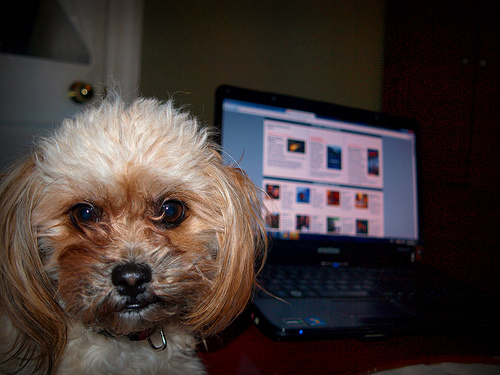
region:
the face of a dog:
[14, 95, 309, 372]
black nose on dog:
[110, 258, 147, 300]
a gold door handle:
[63, 72, 97, 114]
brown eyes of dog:
[49, 184, 229, 246]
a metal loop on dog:
[136, 328, 185, 363]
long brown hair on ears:
[183, 152, 286, 357]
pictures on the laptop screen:
[251, 119, 421, 240]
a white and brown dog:
[0, 83, 232, 372]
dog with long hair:
[1, 108, 266, 358]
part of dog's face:
[93, 246, 169, 329]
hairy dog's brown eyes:
[53, 178, 202, 247]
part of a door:
[15, 17, 155, 157]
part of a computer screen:
[243, 80, 348, 255]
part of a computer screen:
[210, 73, 264, 254]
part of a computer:
[287, 218, 388, 338]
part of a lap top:
[194, 50, 357, 372]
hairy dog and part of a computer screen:
[18, 45, 297, 354]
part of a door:
[46, 57, 113, 124]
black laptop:
[205, 100, 477, 366]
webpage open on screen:
[223, 107, 414, 238]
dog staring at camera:
[15, 102, 250, 373]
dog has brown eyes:
[49, 191, 190, 226]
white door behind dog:
[5, 56, 140, 197]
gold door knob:
[65, 80, 92, 101]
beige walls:
[140, 0, 375, 155]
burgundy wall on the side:
[380, 5, 495, 374]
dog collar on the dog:
[85, 320, 175, 350]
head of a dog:
[25, 107, 256, 329]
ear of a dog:
[6, 139, 76, 232]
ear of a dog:
[188, 162, 264, 252]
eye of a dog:
[51, 199, 116, 235]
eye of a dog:
[135, 187, 205, 247]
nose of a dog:
[108, 262, 165, 304]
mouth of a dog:
[90, 287, 181, 340]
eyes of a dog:
[62, 177, 220, 247]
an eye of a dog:
[53, 194, 117, 239]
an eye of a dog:
[142, 161, 206, 229]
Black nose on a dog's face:
[106, 259, 155, 298]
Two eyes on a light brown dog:
[70, 196, 187, 226]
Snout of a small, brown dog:
[63, 244, 193, 330]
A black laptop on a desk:
[214, 78, 473, 341]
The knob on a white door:
[67, 76, 94, 104]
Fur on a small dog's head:
[96, 120, 166, 190]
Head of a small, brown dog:
[5, 89, 250, 335]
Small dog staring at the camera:
[0, 88, 258, 373]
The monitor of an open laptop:
[214, 82, 429, 257]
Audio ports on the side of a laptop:
[251, 311, 261, 324]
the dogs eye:
[65, 194, 97, 225]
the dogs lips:
[118, 293, 148, 320]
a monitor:
[221, 98, 431, 258]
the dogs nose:
[110, 266, 153, 294]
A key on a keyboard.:
[281, 280, 293, 293]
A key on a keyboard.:
[291, 290, 301, 297]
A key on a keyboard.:
[301, 287, 313, 296]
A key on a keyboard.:
[311, 268, 327, 283]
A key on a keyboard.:
[368, 276, 380, 286]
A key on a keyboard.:
[405, 276, 417, 286]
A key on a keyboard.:
[276, 272, 298, 286]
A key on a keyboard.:
[261, 270, 273, 283]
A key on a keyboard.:
[276, 288, 288, 303]